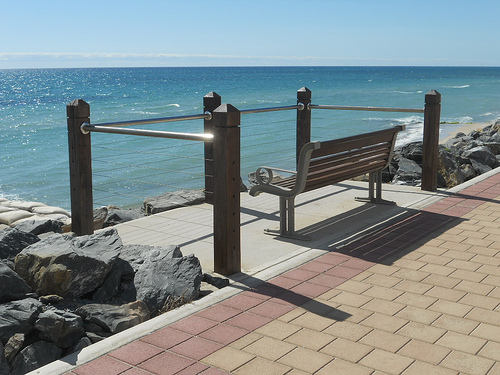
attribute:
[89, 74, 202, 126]
water — blue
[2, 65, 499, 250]
water — blue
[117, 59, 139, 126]
water — blue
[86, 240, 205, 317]
rocks — large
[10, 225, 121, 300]
rocks — large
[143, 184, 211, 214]
rocks — large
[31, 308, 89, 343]
rocks — large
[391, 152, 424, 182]
rocks — large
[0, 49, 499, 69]
clouds — white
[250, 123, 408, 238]
bench — empty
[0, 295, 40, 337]
rock — grey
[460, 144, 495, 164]
rock — grey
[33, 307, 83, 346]
rock — grey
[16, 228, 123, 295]
rock — grey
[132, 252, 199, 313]
rock — grey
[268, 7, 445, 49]
blue sky — clear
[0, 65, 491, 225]
water — blue, ripples